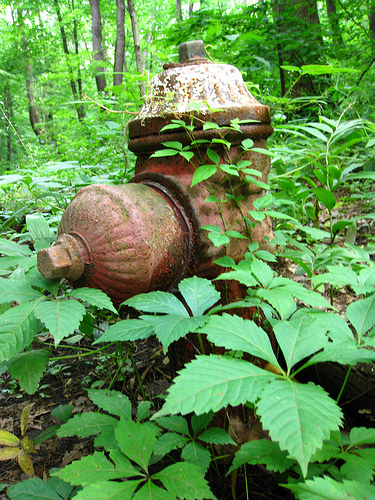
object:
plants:
[91, 254, 374, 479]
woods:
[0, 0, 375, 498]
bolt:
[178, 39, 207, 64]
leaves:
[255, 378, 346, 481]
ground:
[0, 177, 374, 498]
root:
[212, 469, 232, 499]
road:
[0, 137, 375, 499]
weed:
[0, 212, 375, 499]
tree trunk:
[269, 0, 337, 122]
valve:
[36, 177, 196, 311]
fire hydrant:
[36, 39, 284, 374]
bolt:
[36, 242, 70, 281]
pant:
[141, 64, 253, 114]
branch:
[337, 0, 375, 86]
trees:
[0, 0, 375, 172]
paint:
[169, 66, 243, 104]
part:
[118, 110, 136, 114]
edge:
[206, 426, 230, 437]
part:
[223, 420, 242, 444]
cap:
[37, 181, 189, 310]